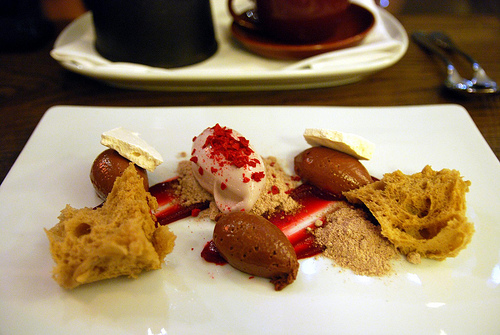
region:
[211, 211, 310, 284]
A piece of food.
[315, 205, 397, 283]
A piece of food.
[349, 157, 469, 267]
A piece of food.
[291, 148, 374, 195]
A piece of food.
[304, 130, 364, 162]
A piece of food.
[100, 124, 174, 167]
A piece of food.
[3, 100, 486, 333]
the white plate is rectangular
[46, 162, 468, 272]
pieces of yellow bread are on each side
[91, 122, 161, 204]
a wedge of cheese is on a cone of hummus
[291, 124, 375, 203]
a wedge of white chocolate is on a dollop of ice cream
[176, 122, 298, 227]
yogurt pudding is on brown sugar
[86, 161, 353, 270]
all the desserts are on a smear of raspberry glaze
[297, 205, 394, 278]
a spoonful of brown sugar on strawberry reduction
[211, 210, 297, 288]
chocolate pudding placed on raspberries' reduction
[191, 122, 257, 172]
coconut flakes dyed red on vanilla pudding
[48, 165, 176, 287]
chunks of yellow bread pudding to dip with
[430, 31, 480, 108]
two silver ware on table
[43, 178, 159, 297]
orange crusty piece of bread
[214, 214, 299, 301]
a scoop of chocolate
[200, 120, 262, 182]
red sprinkles on cream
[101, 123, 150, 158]
white chocolate on dark chocolate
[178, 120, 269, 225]
cream on top of crumbles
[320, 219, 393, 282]
brown powder on plate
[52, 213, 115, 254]
hole in a piece of bread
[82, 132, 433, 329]
desert on a plate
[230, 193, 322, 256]
chocolate cream on top of raspberry spread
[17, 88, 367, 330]
food on white dinner plate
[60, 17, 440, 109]
second white plate with food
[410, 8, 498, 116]
two utensils in photograph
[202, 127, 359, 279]
red sauce on white serving plate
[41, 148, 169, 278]
brown food on serving plate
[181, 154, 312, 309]
chocolate food on white plate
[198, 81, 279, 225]
red flakes on white food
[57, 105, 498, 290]
different colored food on white plate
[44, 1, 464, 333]
two white plates with food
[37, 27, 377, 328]
white plates on brown table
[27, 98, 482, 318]
pastries on a plate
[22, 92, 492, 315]
different kinds of desserts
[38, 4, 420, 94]
coffee mugs on a plate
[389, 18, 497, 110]
silverware on a table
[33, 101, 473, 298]
small appetizing pastries on display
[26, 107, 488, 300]
assorted candies on a plate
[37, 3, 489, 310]
coffee and dessert on a table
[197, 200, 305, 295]
a small chocolate dessert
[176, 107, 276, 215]
a small cream dessert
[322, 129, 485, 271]
a small bread dessert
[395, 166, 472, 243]
a delicious piece of cake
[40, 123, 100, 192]
a white table mat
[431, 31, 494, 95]
a pair of spoons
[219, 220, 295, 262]
brown delicious piece of chocolate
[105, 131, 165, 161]
a piece of butter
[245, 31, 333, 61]
a saucer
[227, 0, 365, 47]
a cup on a saucer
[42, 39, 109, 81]
a white piece of napkin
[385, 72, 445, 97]
a dark brown table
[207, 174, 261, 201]
a white piece of cheese